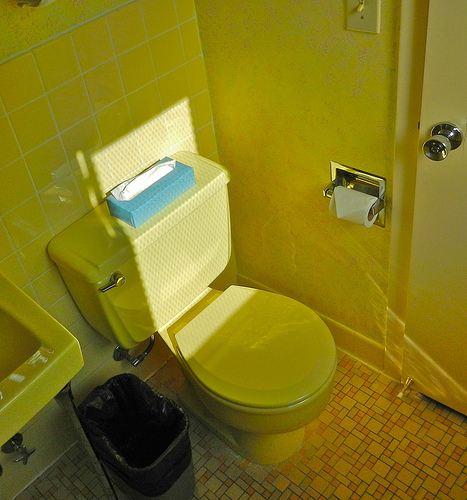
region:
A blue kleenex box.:
[104, 156, 196, 228]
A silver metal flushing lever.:
[98, 271, 125, 293]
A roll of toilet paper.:
[326, 186, 379, 228]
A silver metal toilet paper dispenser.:
[322, 160, 386, 230]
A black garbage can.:
[74, 373, 196, 499]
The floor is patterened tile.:
[337, 351, 465, 498]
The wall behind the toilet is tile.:
[0, 0, 238, 498]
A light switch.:
[344, 0, 380, 34]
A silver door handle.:
[420, 120, 464, 162]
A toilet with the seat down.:
[45, 150, 338, 466]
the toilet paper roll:
[327, 184, 378, 228]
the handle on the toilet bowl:
[101, 272, 125, 293]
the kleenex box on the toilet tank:
[106, 156, 197, 228]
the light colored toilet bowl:
[46, 150, 338, 466]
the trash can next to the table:
[82, 372, 196, 497]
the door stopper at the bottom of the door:
[397, 375, 413, 399]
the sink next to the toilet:
[0, 271, 83, 447]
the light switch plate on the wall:
[345, 1, 381, 31]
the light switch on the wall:
[356, 1, 363, 11]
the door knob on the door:
[421, 121, 461, 161]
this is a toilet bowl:
[171, 287, 353, 475]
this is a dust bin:
[79, 367, 199, 498]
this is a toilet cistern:
[49, 149, 246, 354]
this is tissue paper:
[105, 151, 195, 226]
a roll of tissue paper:
[328, 179, 390, 242]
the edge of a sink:
[0, 282, 86, 452]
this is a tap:
[13, 439, 44, 468]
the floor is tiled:
[30, 356, 463, 498]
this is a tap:
[413, 123, 462, 171]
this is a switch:
[339, 0, 387, 44]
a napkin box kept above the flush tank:
[91, 141, 202, 221]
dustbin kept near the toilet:
[80, 373, 198, 489]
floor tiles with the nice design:
[364, 392, 451, 497]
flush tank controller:
[98, 267, 132, 297]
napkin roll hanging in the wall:
[317, 178, 391, 234]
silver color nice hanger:
[327, 160, 391, 230]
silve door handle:
[418, 124, 464, 167]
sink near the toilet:
[0, 275, 72, 448]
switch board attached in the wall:
[331, 0, 399, 52]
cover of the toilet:
[182, 295, 330, 396]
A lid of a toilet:
[193, 294, 319, 398]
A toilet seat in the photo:
[198, 292, 332, 472]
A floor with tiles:
[341, 424, 439, 488]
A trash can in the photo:
[94, 389, 202, 482]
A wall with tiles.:
[27, 92, 109, 160]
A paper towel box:
[105, 154, 189, 215]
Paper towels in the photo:
[117, 156, 182, 199]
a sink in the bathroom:
[6, 299, 66, 392]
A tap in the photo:
[11, 430, 38, 470]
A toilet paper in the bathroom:
[325, 179, 378, 229]